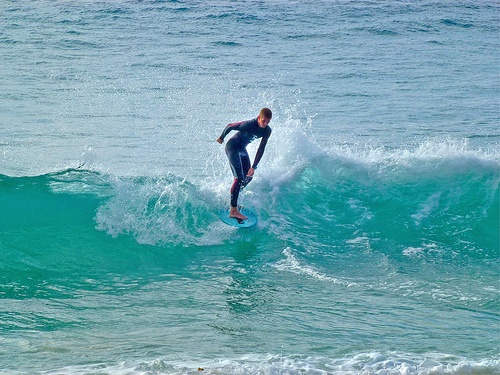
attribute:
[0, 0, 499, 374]
water — clear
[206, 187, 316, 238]
surfboard — blue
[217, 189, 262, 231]
surfboard — blue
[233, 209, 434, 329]
water — body